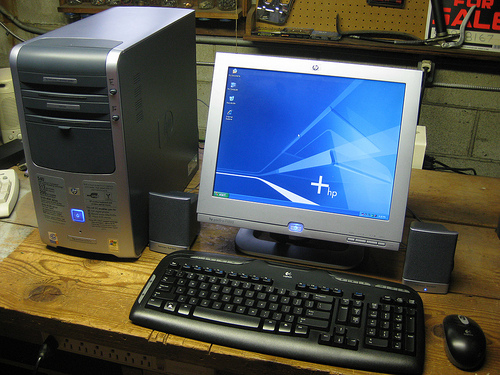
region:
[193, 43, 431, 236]
computer monitor on desk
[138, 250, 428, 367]
black keyboard on desk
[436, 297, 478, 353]
black mouse on desk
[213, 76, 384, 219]
blue screen on computer monitor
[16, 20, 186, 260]
silver CPU of computer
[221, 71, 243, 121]
icons on computer screen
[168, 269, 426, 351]
keys on black keyboard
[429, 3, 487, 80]
black, orange, and white sign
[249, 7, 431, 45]
pegboard against wall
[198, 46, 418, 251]
gray frame of computer monitor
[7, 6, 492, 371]
computer equipment on wooden table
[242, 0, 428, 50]
perforated board with tools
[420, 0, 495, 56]
red sign with hand-written numbers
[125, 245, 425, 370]
black keyboard and black keys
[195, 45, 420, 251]
silver monitor with blue image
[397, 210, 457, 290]
speaker with dot of blue light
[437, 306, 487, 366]
oval mouse with shiny spot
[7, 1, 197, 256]
bulky computer hardware with blue light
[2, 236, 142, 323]
circles and curves on grainy wood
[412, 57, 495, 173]
plug and wiring on concrete-block wall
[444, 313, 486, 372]
Black computer mouse.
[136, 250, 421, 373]
Black computer keyboard.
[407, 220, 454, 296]
Small grey speaker.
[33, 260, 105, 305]
Part of wood table.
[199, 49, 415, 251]
Grey desktop computer screen.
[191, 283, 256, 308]
Buttons on the keyboard.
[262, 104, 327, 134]
Blue computer background.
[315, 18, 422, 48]
A tool in the background.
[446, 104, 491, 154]
Part of the wall.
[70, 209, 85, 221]
Blue glowing light.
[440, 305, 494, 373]
black wireless mouse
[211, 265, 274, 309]
keys on the keyboard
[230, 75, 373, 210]
blue screen on the monitor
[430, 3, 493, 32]
black sign that says for sale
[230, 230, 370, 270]
stand that the monitor sits on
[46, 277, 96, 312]
tan wooden table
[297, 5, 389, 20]
brown peg board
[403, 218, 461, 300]
gray speaker beside the monitor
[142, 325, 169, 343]
scratch marks in the table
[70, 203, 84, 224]
blue apple logo on the tower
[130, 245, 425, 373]
key board on a desk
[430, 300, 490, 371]
mouse on a desk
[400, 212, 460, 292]
speaker on a desk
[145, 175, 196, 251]
speaker on a desk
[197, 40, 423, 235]
monitor on a desk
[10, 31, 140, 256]
gray desk top computer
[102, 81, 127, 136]
button on a computer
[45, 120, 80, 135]
button on a computer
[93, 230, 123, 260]
sticker on a computer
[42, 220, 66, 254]
sticker on a computer